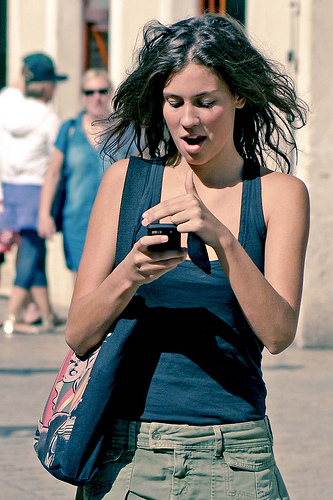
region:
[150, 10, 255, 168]
the head of a woman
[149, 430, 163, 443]
a button on the woman's pants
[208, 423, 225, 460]
a gray belt loop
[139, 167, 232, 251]
the hand of the woman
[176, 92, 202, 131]
the nose of the woman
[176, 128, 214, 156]
the mouth of the woman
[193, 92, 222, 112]
the eye of the woman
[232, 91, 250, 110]
the ear of the woman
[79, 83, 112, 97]
a pair of sunglasses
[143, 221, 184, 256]
a black cell phone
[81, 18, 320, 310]
a woman staring at her phone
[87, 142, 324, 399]
a woman holding onto her phone with both hands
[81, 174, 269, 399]
a woman holding onto a phone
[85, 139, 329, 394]
woman wearing a dark tank top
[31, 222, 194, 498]
a woman with a tote bag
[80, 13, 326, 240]
a woman with black hair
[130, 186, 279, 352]
woman holding onto a black phone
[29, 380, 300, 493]
woman with green bottoms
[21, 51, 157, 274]
man with a black hat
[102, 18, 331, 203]
woman with wavy black hair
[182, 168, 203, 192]
a thumb of a person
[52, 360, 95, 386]
print on a bag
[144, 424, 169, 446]
button on the waist of pants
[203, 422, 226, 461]
a belt loop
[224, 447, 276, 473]
a pocket flap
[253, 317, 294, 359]
an elbow of a person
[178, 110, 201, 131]
a nose on a face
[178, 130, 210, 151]
a mouth on a face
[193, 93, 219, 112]
an eye on a face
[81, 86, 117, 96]
sunglasses on a face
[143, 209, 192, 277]
black phone girl is holding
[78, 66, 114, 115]
woman wearing sunglasses behind girl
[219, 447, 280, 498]
pocket on front of girl's pants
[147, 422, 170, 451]
waist button on pants of girl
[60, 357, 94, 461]
part of design on front of girl's purse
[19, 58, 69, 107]
person wearing cap behind girl with phone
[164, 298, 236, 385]
shadow on girl's blue top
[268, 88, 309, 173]
part of girl's hair blowing in wind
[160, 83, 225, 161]
expression on girl's face as she looks at phone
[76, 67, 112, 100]
blond hair of woman behind the girl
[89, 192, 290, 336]
woman on black cell phone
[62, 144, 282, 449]
woman in black tank top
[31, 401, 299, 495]
woman in beige skirt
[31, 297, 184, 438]
woman with black bag with picture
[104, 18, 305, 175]
woman with brown hair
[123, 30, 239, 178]
woman looks surprised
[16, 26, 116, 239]
two people in background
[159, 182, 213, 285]
women with cell phone and case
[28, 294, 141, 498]
red on the black bag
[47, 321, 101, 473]
red and yellow and beige on black bag